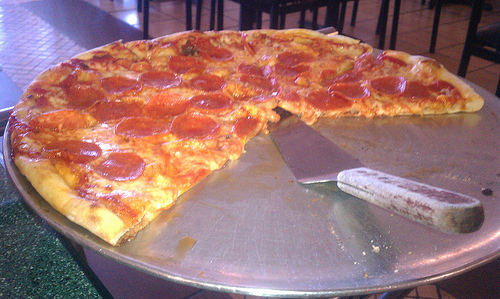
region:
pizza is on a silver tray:
[6, 11, 496, 291]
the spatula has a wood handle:
[257, 87, 497, 254]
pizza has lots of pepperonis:
[8, 16, 495, 257]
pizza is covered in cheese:
[8, 21, 498, 246]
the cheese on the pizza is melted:
[7, 17, 489, 242]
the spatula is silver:
[239, 76, 490, 251]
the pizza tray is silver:
[4, 16, 497, 296]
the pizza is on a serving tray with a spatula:
[6, 18, 498, 278]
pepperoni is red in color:
[7, 18, 490, 254]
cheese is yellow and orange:
[6, 17, 490, 260]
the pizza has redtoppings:
[29, 55, 221, 167]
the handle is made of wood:
[343, 158, 485, 231]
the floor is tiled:
[409, 16, 444, 49]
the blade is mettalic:
[278, 115, 340, 185]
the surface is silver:
[216, 217, 438, 281]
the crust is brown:
[25, 174, 144, 252]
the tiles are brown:
[407, 19, 462, 46]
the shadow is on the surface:
[328, 214, 394, 257]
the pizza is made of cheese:
[88, 136, 173, 202]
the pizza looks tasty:
[14, 28, 483, 246]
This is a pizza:
[30, 14, 444, 279]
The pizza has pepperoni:
[30, 28, 459, 202]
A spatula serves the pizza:
[263, 78, 477, 261]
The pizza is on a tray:
[16, 20, 490, 279]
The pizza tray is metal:
[50, 23, 449, 250]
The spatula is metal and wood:
[254, 99, 498, 257]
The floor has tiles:
[15, 11, 80, 66]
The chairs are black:
[144, 3, 487, 55]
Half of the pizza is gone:
[27, 46, 493, 207]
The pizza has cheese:
[59, 36, 458, 177]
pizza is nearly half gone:
[10, 24, 499, 287]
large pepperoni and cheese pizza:
[21, 29, 499, 296]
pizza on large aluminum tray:
[11, 19, 478, 292]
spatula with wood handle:
[271, 102, 486, 241]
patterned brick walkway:
[0, 0, 160, 100]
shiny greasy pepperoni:
[99, 147, 148, 183]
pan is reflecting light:
[198, 254, 376, 296]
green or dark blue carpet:
[0, 207, 107, 297]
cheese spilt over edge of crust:
[1, 108, 48, 163]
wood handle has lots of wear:
[339, 166, 488, 244]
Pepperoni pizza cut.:
[15, 40, 475, 211]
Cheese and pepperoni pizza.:
[88, 92, 193, 194]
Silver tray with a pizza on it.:
[175, 210, 300, 280]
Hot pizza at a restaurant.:
[60, 45, 242, 207]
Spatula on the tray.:
[245, 71, 455, 242]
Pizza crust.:
[62, 205, 127, 228]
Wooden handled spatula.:
[346, 151, 486, 239]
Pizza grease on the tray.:
[165, 222, 221, 269]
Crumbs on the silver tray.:
[323, 205, 415, 290]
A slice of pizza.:
[307, 42, 492, 131]